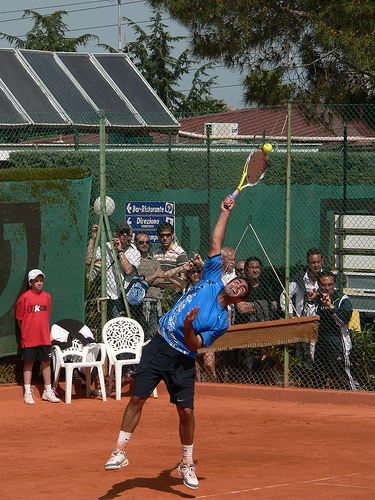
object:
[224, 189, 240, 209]
handle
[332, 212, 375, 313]
window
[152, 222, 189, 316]
man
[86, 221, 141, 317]
man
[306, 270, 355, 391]
man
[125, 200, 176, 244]
sign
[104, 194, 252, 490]
man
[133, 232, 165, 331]
man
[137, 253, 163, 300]
shirt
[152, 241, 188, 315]
shirt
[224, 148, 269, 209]
racket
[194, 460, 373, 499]
line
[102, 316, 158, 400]
chair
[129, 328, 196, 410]
shorts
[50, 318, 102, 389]
jacket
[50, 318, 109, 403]
chair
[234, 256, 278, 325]
man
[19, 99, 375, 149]
roof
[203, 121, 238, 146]
air conditioner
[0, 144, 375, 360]
wall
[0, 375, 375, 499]
court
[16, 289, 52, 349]
shirt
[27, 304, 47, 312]
letter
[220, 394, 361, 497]
ground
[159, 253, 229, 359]
shirt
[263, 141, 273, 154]
ball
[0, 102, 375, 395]
fence